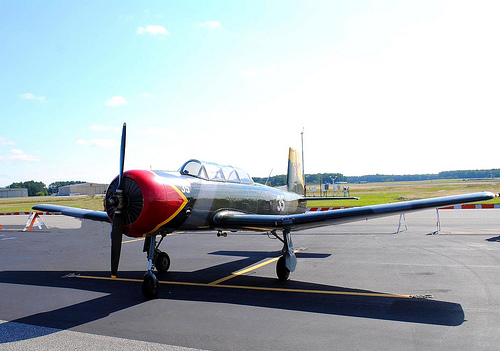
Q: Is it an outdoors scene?
A: Yes, it is outdoors.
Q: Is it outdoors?
A: Yes, it is outdoors.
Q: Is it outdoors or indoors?
A: It is outdoors.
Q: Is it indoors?
A: No, it is outdoors.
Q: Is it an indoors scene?
A: No, it is outdoors.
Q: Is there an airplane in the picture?
A: Yes, there is an airplane.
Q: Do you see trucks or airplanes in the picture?
A: Yes, there is an airplane.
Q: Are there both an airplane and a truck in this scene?
A: No, there is an airplane but no trucks.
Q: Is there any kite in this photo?
A: No, there are no kites.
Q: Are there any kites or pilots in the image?
A: No, there are no kites or pilots.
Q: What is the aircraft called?
A: The aircraft is an airplane.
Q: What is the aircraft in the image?
A: The aircraft is an airplane.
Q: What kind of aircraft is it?
A: The aircraft is an airplane.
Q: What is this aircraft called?
A: This is an airplane.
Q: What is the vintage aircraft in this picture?
A: The aircraft is an airplane.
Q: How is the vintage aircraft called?
A: The aircraft is an airplane.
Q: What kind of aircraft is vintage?
A: The aircraft is an airplane.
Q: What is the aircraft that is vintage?
A: The aircraft is an airplane.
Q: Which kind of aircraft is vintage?
A: The aircraft is an airplane.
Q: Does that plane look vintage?
A: Yes, the plane is vintage.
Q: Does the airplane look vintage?
A: Yes, the airplane is vintage.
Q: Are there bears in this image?
A: No, there are no bears.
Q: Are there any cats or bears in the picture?
A: No, there are no bears or cats.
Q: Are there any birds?
A: No, there are no birds.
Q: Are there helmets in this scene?
A: No, there are no helmets.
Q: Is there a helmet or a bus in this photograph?
A: No, there are no helmets or buses.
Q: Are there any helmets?
A: No, there are no helmets.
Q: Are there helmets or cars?
A: No, there are no helmets or cars.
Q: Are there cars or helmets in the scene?
A: No, there are no helmets or cars.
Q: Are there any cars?
A: No, there are no cars.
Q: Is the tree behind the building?
A: Yes, the tree is behind the building.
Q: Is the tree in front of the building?
A: No, the tree is behind the building.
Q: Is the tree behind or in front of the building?
A: The tree is behind the building.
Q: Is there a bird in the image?
A: No, there are no birds.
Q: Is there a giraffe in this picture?
A: No, there are no giraffes.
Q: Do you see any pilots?
A: No, there are no pilots.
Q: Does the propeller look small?
A: Yes, the propeller is small.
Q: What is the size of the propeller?
A: The propeller is small.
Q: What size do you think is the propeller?
A: The propeller is small.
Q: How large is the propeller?
A: The propeller is small.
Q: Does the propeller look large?
A: No, the propeller is small.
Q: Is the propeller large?
A: No, the propeller is small.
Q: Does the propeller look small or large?
A: The propeller is small.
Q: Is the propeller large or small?
A: The propeller is small.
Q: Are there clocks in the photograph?
A: No, there are no clocks.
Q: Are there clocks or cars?
A: No, there are no clocks or cars.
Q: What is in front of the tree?
A: The building is in front of the tree.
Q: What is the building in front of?
A: The building is in front of the tree.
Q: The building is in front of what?
A: The building is in front of the tree.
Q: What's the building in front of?
A: The building is in front of the tree.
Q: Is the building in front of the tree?
A: Yes, the building is in front of the tree.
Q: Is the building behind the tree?
A: No, the building is in front of the tree.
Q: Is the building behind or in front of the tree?
A: The building is in front of the tree.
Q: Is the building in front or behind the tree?
A: The building is in front of the tree.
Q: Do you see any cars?
A: No, there are no cars.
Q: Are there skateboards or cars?
A: No, there are no cars or skateboards.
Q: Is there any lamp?
A: No, there are no lamps.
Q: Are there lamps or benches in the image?
A: No, there are no lamps or benches.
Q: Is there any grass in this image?
A: Yes, there is grass.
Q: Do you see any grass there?
A: Yes, there is grass.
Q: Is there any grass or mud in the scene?
A: Yes, there is grass.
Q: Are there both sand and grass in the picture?
A: No, there is grass but no sand.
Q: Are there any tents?
A: No, there are no tents.